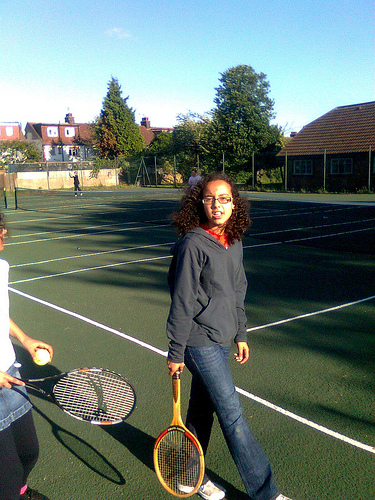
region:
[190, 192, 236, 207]
A PAIR OF GLASSES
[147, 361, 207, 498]
A YELLOW AND RED TENNIS RACKET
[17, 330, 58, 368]
SOMEONE HOLDING A TENNIS BALL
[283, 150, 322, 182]
A WINDOW ON A BUILDING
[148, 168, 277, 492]
A GIRL HOLDING A TENNIS RACKET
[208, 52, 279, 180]
A TREE IN THE DISTANCE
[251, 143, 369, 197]
A CHAIN LINK FENCE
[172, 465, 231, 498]
A WHITE TENNIS SHOE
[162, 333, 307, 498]
A PAIR OF BLUE JEANS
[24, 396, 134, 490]
THE SHADOW OF A TENNIS RACKET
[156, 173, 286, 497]
the woman is walking by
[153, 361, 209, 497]
the woman is holding a racket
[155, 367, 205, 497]
the racket is made of wood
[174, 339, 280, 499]
the woman is wearing blue jeans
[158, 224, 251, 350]
the girl is wearing a sweatshirt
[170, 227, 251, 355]
the sweatshirt is black in color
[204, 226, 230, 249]
the woman is wearing a red undershirt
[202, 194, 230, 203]
the woman is wearing glasses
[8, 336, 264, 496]
the woman is casting a shadow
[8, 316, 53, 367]
a woman is holding a tennis ball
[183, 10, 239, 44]
part of the sky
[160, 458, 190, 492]
part of a racket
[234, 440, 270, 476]
part of a jeans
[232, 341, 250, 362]
part of a left hand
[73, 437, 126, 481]
part of a shadow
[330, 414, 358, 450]
part of a white line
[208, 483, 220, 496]
part of a shoe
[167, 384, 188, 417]
handle of a racket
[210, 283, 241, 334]
part of a jumoper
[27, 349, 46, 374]
part of a tennis ball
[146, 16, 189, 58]
part of the sky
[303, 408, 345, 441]
part of a white line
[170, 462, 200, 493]
part of a racket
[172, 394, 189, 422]
handle of a racket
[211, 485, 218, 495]
part of a shoe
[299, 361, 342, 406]
part of a tennis court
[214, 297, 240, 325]
part of a jumper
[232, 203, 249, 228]
hair of a lady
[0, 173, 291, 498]
two girls on a tennis court carrying tennis rackets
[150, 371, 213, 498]
a wooden tennis racket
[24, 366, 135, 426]
an aluminum tennis racket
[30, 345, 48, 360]
a tennis ball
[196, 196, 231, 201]
a girl's glasses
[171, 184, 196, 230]
a girl's brown curly hair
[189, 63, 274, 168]
a large tree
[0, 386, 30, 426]
a girl's blue denim skirt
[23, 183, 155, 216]
a net on a tennis court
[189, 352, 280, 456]
a girl's blue jeans